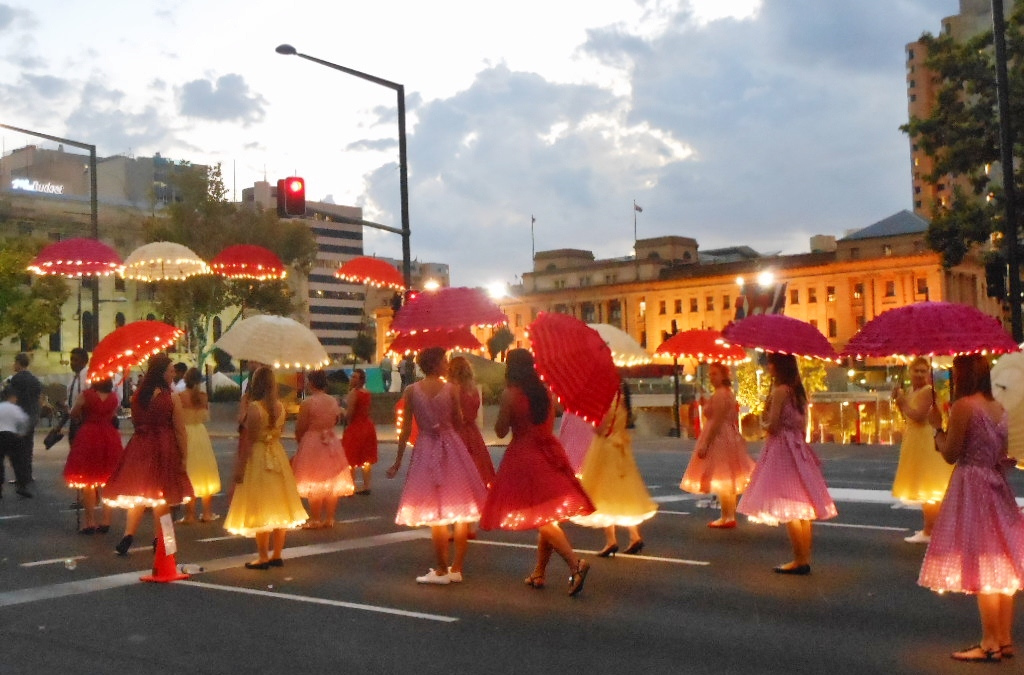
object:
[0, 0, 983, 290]
blue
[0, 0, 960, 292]
sky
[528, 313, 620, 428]
umbrella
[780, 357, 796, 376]
brown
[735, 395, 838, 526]
pink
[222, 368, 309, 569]
girl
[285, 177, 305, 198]
red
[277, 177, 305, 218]
light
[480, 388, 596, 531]
red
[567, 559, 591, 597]
flats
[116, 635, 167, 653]
grey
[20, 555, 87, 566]
lines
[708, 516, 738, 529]
shoes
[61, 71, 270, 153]
clouds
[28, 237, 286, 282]
umbrellas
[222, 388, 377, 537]
dresses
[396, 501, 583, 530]
lights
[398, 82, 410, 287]
pole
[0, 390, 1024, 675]
street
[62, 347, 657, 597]
people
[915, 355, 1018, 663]
girl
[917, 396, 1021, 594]
dress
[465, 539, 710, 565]
white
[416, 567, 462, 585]
shoes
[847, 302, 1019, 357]
pink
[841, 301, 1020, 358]
umbrella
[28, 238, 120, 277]
umbrella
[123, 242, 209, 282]
umbrella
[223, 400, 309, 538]
yellow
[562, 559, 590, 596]
sandals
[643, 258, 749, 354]
building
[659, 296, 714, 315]
windows